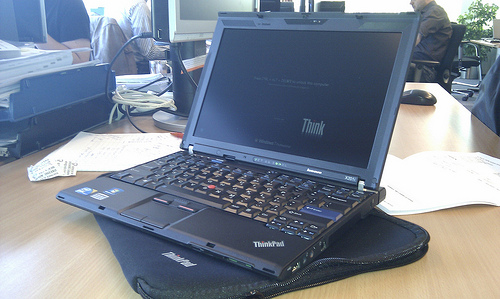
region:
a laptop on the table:
[75, 6, 425, 296]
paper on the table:
[369, 128, 495, 212]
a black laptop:
[52, 13, 422, 278]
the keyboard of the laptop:
[133, 145, 339, 238]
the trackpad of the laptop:
[126, 185, 194, 231]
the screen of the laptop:
[196, 19, 403, 174]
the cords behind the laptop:
[105, 65, 183, 129]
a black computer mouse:
[402, 85, 437, 102]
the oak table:
[3, 209, 83, 285]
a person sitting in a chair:
[411, 2, 458, 78]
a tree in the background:
[459, 2, 494, 37]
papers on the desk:
[384, 152, 498, 215]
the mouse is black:
[394, 82, 443, 111]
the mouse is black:
[387, 67, 457, 128]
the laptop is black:
[57, 6, 416, 295]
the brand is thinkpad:
[67, 16, 456, 296]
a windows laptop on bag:
[52, 22, 486, 295]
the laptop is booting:
[63, 19, 441, 298]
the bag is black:
[78, 113, 323, 298]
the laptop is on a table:
[67, 31, 428, 251]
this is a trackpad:
[116, 189, 227, 257]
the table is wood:
[56, 6, 498, 281]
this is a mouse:
[383, 81, 448, 136]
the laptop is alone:
[25, 21, 495, 283]